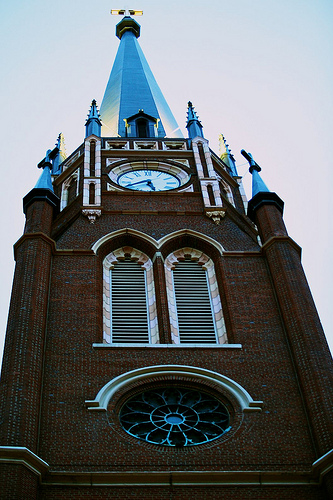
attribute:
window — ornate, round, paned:
[102, 371, 243, 458]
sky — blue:
[11, 15, 82, 86]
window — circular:
[112, 374, 240, 450]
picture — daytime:
[2, 24, 326, 366]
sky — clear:
[162, 4, 331, 96]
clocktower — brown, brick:
[5, 4, 329, 496]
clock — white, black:
[101, 156, 196, 191]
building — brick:
[1, 7, 332, 497]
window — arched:
[93, 240, 166, 353]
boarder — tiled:
[96, 243, 162, 346]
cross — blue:
[239, 149, 270, 196]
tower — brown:
[37, 267, 89, 379]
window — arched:
[101, 248, 151, 346]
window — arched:
[170, 251, 218, 343]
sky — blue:
[2, 1, 322, 361]